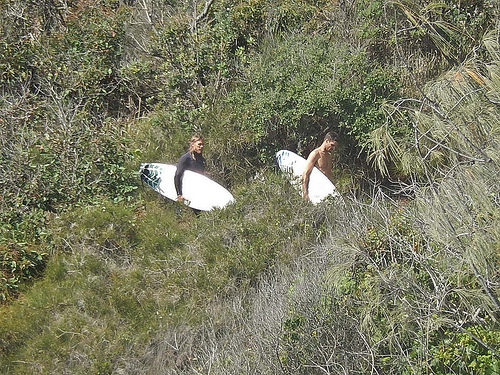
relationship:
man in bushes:
[166, 129, 209, 200] [7, 9, 496, 375]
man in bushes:
[294, 118, 346, 203] [7, 9, 496, 375]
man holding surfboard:
[166, 129, 209, 200] [136, 160, 242, 217]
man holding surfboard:
[294, 118, 346, 203] [270, 145, 350, 224]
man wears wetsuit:
[166, 129, 209, 200] [173, 151, 207, 193]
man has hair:
[166, 129, 209, 200] [187, 133, 204, 161]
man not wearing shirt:
[294, 118, 346, 203] [299, 149, 338, 181]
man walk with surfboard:
[166, 129, 209, 200] [136, 160, 242, 217]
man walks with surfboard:
[294, 118, 346, 203] [270, 145, 350, 224]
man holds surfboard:
[294, 118, 346, 203] [270, 145, 350, 224]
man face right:
[166, 129, 209, 200] [369, 0, 492, 368]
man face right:
[294, 118, 346, 203] [369, 0, 492, 368]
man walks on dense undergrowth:
[166, 129, 209, 200] [7, 9, 496, 375]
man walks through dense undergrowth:
[294, 118, 346, 203] [7, 9, 496, 375]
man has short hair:
[294, 118, 346, 203] [323, 129, 343, 142]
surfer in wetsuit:
[166, 129, 209, 200] [173, 151, 207, 193]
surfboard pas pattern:
[136, 160, 242, 217] [136, 160, 168, 197]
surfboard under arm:
[136, 160, 242, 217] [171, 158, 195, 207]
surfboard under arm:
[270, 145, 350, 224] [299, 151, 321, 207]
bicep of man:
[304, 152, 319, 171] [294, 118, 346, 203]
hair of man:
[187, 130, 200, 162] [166, 129, 209, 200]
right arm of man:
[171, 158, 195, 207] [166, 129, 209, 200]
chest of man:
[319, 155, 338, 176] [294, 118, 346, 203]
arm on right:
[171, 158, 195, 207] [172, 159, 186, 195]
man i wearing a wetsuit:
[173, 151, 207, 193] [171, 150, 209, 193]